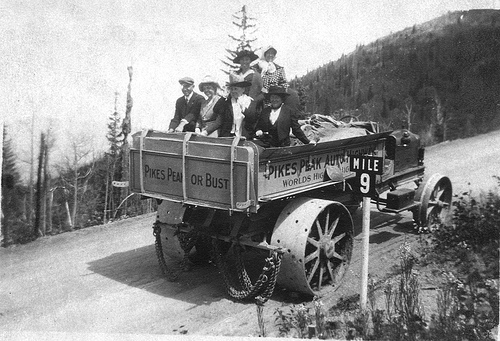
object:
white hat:
[195, 75, 225, 92]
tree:
[103, 89, 123, 217]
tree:
[50, 133, 98, 231]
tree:
[32, 131, 55, 235]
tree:
[0, 122, 22, 244]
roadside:
[0, 126, 178, 341]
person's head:
[198, 75, 224, 98]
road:
[3, 260, 204, 337]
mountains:
[1, 9, 500, 181]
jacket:
[254, 102, 311, 148]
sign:
[351, 152, 385, 198]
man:
[165, 77, 206, 134]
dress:
[252, 60, 287, 89]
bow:
[258, 60, 277, 78]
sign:
[142, 164, 230, 190]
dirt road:
[0, 133, 498, 341]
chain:
[212, 239, 284, 305]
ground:
[373, 232, 419, 268]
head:
[239, 56, 252, 68]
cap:
[178, 76, 194, 85]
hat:
[225, 74, 254, 88]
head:
[227, 82, 246, 98]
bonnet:
[232, 49, 260, 63]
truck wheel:
[268, 198, 356, 299]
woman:
[252, 85, 316, 147]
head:
[264, 48, 277, 63]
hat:
[263, 85, 291, 99]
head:
[202, 84, 217, 99]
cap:
[198, 75, 222, 93]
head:
[269, 94, 284, 108]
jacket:
[168, 91, 206, 131]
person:
[260, 44, 289, 90]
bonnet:
[261, 44, 278, 53]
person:
[254, 85, 317, 147]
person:
[212, 73, 258, 137]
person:
[194, 74, 225, 138]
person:
[230, 50, 263, 100]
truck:
[129, 115, 453, 299]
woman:
[232, 47, 258, 98]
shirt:
[270, 103, 285, 126]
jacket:
[213, 96, 255, 137]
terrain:
[0, 16, 500, 197]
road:
[0, 144, 498, 341]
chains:
[152, 222, 202, 282]